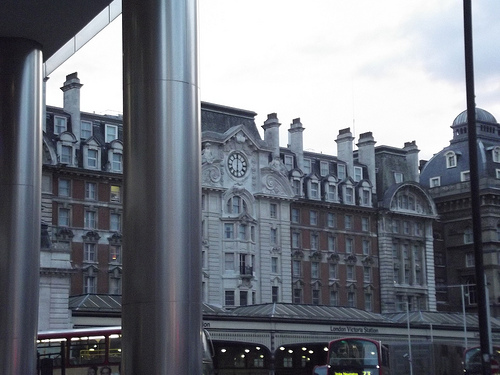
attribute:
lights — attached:
[209, 344, 345, 368]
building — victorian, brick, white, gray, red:
[54, 60, 460, 310]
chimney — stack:
[264, 98, 355, 174]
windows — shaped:
[287, 195, 391, 302]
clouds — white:
[267, 8, 404, 105]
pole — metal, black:
[443, 19, 500, 200]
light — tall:
[452, 55, 484, 259]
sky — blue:
[294, 28, 468, 63]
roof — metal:
[269, 121, 362, 185]